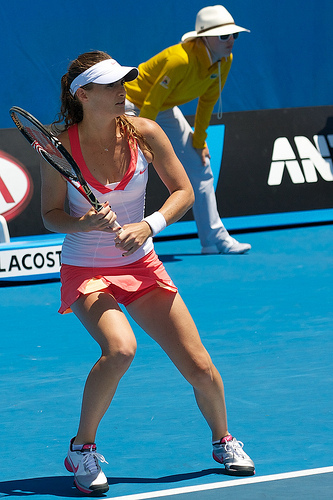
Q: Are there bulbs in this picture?
A: No, there are no bulbs.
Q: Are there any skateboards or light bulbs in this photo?
A: No, there are no light bulbs or skateboards.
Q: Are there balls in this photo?
A: No, there are no balls.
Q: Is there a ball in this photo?
A: No, there are no balls.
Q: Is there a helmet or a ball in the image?
A: No, there are no balls or helmets.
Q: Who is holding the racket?
A: The player is holding the racket.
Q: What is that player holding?
A: The player is holding the racket.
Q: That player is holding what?
A: The player is holding the racket.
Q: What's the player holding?
A: The player is holding the racket.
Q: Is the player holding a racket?
A: Yes, the player is holding a racket.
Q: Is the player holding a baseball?
A: No, the player is holding a racket.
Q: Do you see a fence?
A: No, there are no fences.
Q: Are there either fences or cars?
A: No, there are no fences or cars.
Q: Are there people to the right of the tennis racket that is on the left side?
A: Yes, there is a person to the right of the tennis racket.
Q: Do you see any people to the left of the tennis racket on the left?
A: No, the person is to the right of the tennis racket.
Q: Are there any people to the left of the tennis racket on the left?
A: No, the person is to the right of the tennis racket.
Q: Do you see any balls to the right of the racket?
A: No, there is a person to the right of the racket.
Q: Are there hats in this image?
A: Yes, there is a hat.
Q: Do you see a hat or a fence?
A: Yes, there is a hat.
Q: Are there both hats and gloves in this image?
A: No, there is a hat but no gloves.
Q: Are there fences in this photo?
A: No, there are no fences.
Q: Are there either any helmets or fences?
A: No, there are no fences or helmets.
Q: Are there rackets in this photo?
A: Yes, there is a racket.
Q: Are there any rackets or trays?
A: Yes, there is a racket.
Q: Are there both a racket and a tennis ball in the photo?
A: No, there is a racket but no tennis balls.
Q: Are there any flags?
A: No, there are no flags.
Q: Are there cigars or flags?
A: No, there are no flags or cigars.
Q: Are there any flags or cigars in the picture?
A: No, there are no flags or cigars.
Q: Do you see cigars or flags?
A: No, there are no flags or cigars.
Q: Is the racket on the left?
A: Yes, the racket is on the left of the image.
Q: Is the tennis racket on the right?
A: No, the tennis racket is on the left of the image.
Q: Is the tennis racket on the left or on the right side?
A: The tennis racket is on the left of the image.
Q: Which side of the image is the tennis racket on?
A: The tennis racket is on the left of the image.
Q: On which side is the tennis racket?
A: The tennis racket is on the left of the image.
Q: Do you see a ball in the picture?
A: No, there are no balls.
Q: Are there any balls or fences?
A: No, there are no balls or fences.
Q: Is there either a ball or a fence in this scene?
A: No, there are no balls or fences.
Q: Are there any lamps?
A: No, there are no lamps.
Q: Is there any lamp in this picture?
A: No, there are no lamps.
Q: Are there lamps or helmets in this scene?
A: No, there are no lamps or helmets.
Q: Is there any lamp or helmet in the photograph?
A: No, there are no lamps or helmets.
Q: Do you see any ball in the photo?
A: No, there are no balls.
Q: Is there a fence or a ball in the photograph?
A: No, there are no balls or fences.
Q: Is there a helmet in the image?
A: No, there are no helmets.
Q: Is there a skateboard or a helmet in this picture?
A: No, there are no helmets or skateboards.